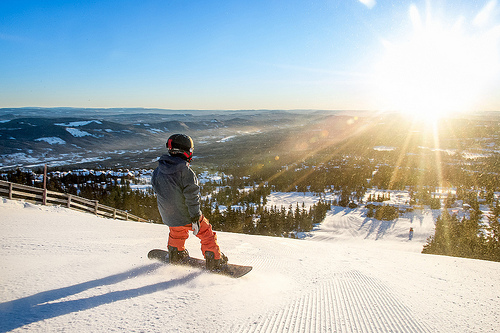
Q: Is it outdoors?
A: Yes, it is outdoors.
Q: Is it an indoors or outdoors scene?
A: It is outdoors.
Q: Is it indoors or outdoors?
A: It is outdoors.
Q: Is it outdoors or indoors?
A: It is outdoors.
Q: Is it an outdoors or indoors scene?
A: It is outdoors.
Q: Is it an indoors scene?
A: No, it is outdoors.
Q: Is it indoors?
A: No, it is outdoors.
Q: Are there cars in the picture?
A: No, there are no cars.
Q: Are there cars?
A: No, there are no cars.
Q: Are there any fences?
A: Yes, there is a fence.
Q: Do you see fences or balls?
A: Yes, there is a fence.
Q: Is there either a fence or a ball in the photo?
A: Yes, there is a fence.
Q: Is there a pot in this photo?
A: No, there are no pots.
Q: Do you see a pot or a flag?
A: No, there are no pots or flags.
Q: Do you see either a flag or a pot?
A: No, there are no pots or flags.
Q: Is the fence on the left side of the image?
A: Yes, the fence is on the left of the image.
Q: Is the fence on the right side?
A: No, the fence is on the left of the image.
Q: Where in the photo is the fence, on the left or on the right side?
A: The fence is on the left of the image.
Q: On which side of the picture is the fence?
A: The fence is on the left of the image.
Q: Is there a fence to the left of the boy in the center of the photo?
A: Yes, there is a fence to the left of the boy.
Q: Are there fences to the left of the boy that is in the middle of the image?
A: Yes, there is a fence to the left of the boy.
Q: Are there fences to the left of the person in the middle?
A: Yes, there is a fence to the left of the boy.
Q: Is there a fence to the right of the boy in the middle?
A: No, the fence is to the left of the boy.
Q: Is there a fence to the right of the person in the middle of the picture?
A: No, the fence is to the left of the boy.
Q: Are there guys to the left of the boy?
A: No, there is a fence to the left of the boy.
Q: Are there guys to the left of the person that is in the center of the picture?
A: No, there is a fence to the left of the boy.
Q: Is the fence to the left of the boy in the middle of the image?
A: Yes, the fence is to the left of the boy.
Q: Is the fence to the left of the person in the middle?
A: Yes, the fence is to the left of the boy.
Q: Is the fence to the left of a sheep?
A: No, the fence is to the left of the boy.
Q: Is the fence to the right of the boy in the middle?
A: No, the fence is to the left of the boy.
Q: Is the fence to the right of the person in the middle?
A: No, the fence is to the left of the boy.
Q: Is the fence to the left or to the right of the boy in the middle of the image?
A: The fence is to the left of the boy.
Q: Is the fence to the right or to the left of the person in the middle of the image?
A: The fence is to the left of the boy.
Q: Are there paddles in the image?
A: No, there are no paddles.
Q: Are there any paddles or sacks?
A: No, there are no paddles or sacks.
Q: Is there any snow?
A: Yes, there is snow.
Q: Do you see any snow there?
A: Yes, there is snow.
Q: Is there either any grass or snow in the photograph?
A: Yes, there is snow.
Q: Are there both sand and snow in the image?
A: No, there is snow but no sand.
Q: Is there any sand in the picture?
A: No, there is no sand.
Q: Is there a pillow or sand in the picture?
A: No, there are no sand or pillows.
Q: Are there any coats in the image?
A: Yes, there is a coat.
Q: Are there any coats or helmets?
A: Yes, there is a coat.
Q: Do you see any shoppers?
A: No, there are no shoppers.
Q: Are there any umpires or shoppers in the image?
A: No, there are no shoppers or umpires.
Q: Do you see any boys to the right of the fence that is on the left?
A: Yes, there is a boy to the right of the fence.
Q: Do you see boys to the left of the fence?
A: No, the boy is to the right of the fence.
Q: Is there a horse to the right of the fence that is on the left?
A: No, there is a boy to the right of the fence.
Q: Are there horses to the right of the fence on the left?
A: No, there is a boy to the right of the fence.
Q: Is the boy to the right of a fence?
A: Yes, the boy is to the right of a fence.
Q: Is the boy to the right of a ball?
A: No, the boy is to the right of a fence.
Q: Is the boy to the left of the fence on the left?
A: No, the boy is to the right of the fence.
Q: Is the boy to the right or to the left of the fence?
A: The boy is to the right of the fence.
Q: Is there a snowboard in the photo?
A: Yes, there is a snowboard.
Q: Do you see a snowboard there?
A: Yes, there is a snowboard.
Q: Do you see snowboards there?
A: Yes, there is a snowboard.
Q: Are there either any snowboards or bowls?
A: Yes, there is a snowboard.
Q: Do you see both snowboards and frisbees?
A: No, there is a snowboard but no frisbees.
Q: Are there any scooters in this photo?
A: No, there are no scooters.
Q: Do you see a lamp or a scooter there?
A: No, there are no scooters or lamps.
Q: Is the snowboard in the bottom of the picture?
A: Yes, the snowboard is in the bottom of the image.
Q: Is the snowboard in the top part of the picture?
A: No, the snowboard is in the bottom of the image.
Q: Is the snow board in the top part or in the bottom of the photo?
A: The snow board is in the bottom of the image.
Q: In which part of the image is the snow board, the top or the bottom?
A: The snow board is in the bottom of the image.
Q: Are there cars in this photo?
A: No, there are no cars.